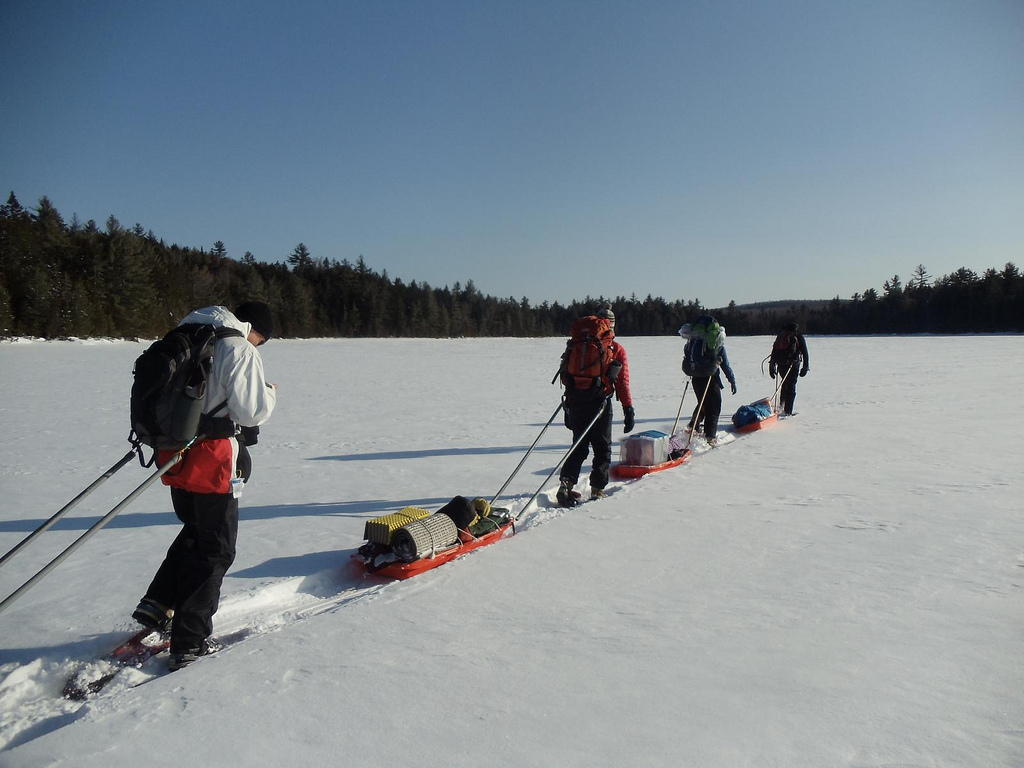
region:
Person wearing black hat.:
[240, 297, 294, 339]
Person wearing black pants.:
[129, 461, 259, 635]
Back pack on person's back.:
[136, 320, 232, 444]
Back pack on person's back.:
[569, 313, 611, 394]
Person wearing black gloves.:
[615, 402, 645, 442]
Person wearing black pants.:
[680, 373, 719, 424]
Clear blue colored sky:
[209, 22, 821, 169]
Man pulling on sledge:
[325, 389, 592, 593]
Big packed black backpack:
[123, 307, 229, 456]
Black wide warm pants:
[128, 496, 250, 667]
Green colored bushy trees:
[306, 260, 509, 328]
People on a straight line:
[100, 294, 859, 538]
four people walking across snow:
[119, 285, 813, 684]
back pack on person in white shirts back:
[124, 314, 248, 455]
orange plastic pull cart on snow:
[340, 388, 615, 598]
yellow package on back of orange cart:
[358, 499, 434, 550]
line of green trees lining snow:
[2, 183, 1020, 345]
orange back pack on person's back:
[552, 309, 622, 404]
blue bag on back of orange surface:
[728, 396, 774, 426]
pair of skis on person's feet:
[42, 604, 257, 718]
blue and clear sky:
[344, 61, 706, 129]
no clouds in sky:
[343, 59, 626, 237]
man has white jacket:
[164, 320, 278, 477]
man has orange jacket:
[552, 322, 648, 439]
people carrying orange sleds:
[293, 351, 788, 576]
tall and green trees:
[7, 249, 422, 316]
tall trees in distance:
[12, 300, 1015, 346]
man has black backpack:
[138, 306, 227, 453]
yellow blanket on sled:
[339, 496, 437, 541]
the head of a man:
[198, 293, 285, 358]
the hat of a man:
[228, 296, 268, 336]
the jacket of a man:
[159, 319, 276, 510]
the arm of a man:
[212, 340, 290, 448]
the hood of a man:
[168, 289, 251, 346]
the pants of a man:
[137, 492, 246, 660]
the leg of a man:
[179, 515, 244, 636]